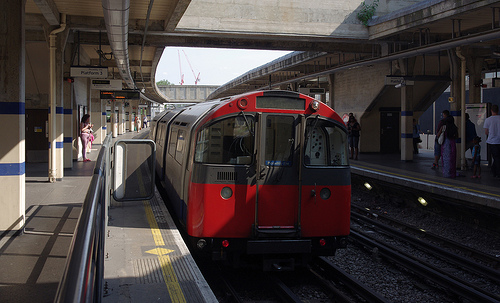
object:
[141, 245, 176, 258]
paint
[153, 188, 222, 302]
paint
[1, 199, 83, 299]
shadows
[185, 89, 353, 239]
paint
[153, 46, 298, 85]
sky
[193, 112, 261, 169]
windows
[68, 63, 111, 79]
sign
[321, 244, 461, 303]
pebbles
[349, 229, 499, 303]
tracks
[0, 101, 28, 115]
paint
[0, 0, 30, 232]
pillar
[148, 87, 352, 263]
train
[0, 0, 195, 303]
station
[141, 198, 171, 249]
line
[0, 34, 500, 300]
train platform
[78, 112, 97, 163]
lady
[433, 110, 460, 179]
people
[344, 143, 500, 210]
train platform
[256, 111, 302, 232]
door